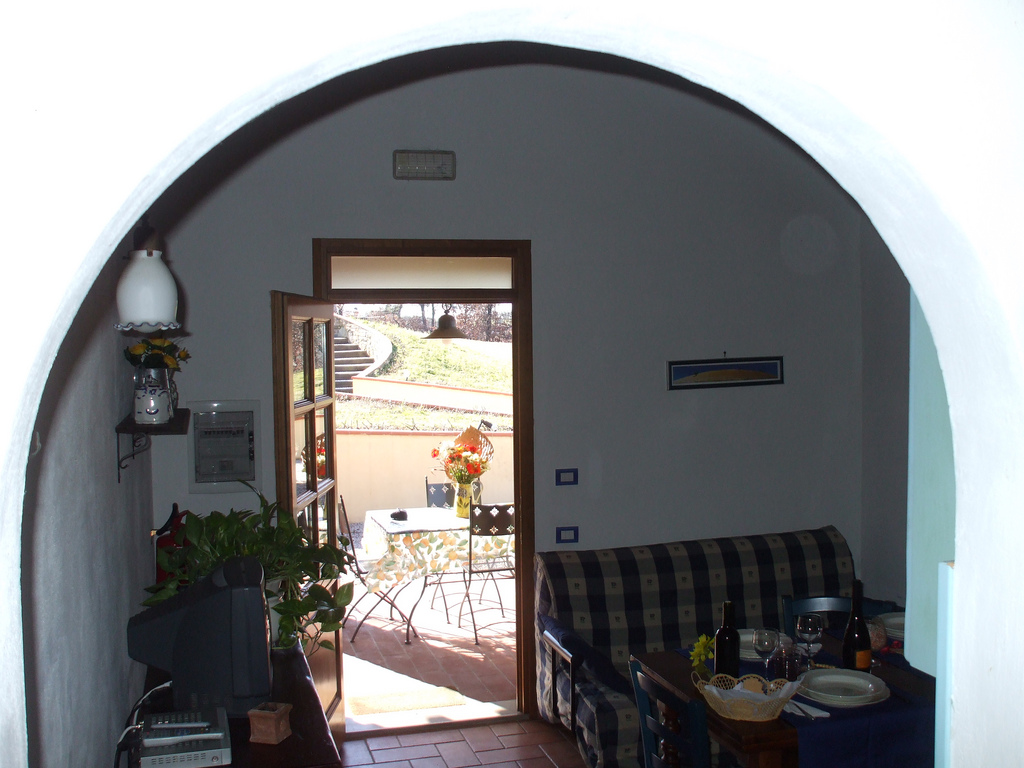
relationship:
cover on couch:
[525, 519, 862, 766] [525, 522, 857, 766]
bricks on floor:
[307, 699, 565, 763] [112, 710, 592, 762]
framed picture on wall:
[704, 335, 859, 438] [569, 160, 690, 281]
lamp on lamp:
[114, 228, 184, 334] [104, 235, 184, 337]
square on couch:
[596, 569, 634, 607] [520, 531, 890, 732]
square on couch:
[614, 563, 643, 594] [576, 516, 944, 738]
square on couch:
[637, 563, 657, 589] [504, 501, 922, 746]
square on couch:
[638, 603, 678, 638] [538, 530, 935, 762]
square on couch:
[635, 560, 667, 590] [534, 533, 901, 765]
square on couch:
[554, 596, 598, 633] [534, 533, 901, 765]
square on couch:
[706, 567, 733, 596] [518, 519, 908, 761]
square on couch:
[731, 580, 771, 617] [550, 529, 819, 624]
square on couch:
[774, 554, 800, 584] [522, 516, 886, 752]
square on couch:
[556, 624, 611, 687] [525, 522, 857, 766]